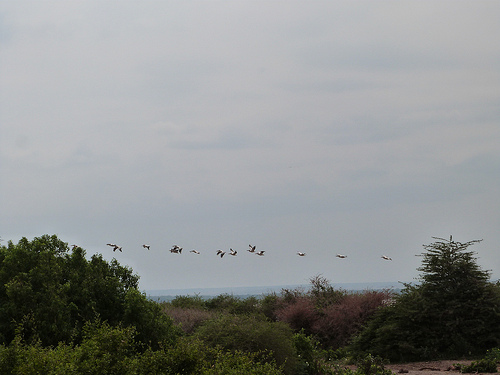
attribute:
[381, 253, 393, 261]
bird — flying, white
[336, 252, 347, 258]
bird — flying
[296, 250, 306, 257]
bird — flying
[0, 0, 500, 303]
sky — grey, cloudy, blue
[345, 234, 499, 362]
bush — green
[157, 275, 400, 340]
shrubs — green, red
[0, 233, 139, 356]
tree — tall, green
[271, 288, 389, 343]
bushes — red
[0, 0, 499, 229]
clouds — white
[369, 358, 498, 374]
dirt — small